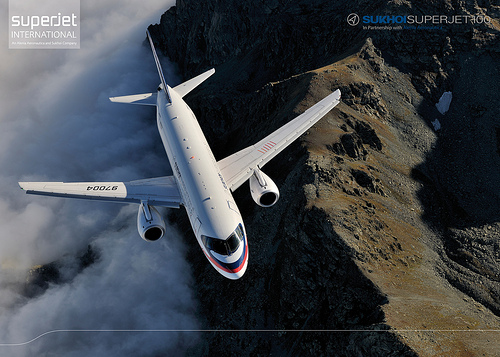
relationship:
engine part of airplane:
[247, 168, 281, 209] [17, 28, 342, 282]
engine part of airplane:
[134, 201, 167, 242] [17, 28, 342, 282]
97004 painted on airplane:
[84, 181, 119, 194] [17, 28, 342, 282]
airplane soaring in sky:
[17, 28, 342, 282] [1, 1, 204, 355]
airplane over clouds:
[17, 28, 342, 282] [8, 63, 105, 163]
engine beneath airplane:
[250, 169, 281, 208] [17, 28, 342, 282]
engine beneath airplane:
[134, 201, 167, 242] [17, 28, 342, 282]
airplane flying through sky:
[17, 28, 342, 282] [1, 1, 204, 355]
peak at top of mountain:
[304, 47, 404, 353] [159, 7, 498, 354]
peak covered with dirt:
[304, 47, 404, 353] [336, 194, 429, 318]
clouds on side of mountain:
[0, 3, 207, 357] [159, 7, 498, 354]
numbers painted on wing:
[86, 185, 119, 191] [17, 174, 183, 208]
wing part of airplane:
[17, 174, 183, 208] [17, 28, 342, 282]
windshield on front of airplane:
[201, 224, 245, 259] [17, 28, 342, 282]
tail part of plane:
[140, 26, 175, 95] [151, 99, 260, 294]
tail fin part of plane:
[169, 68, 213, 103] [151, 99, 260, 294]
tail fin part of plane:
[103, 89, 163, 111] [151, 99, 260, 294]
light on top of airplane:
[187, 154, 196, 162] [17, 28, 342, 282]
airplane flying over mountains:
[17, 28, 342, 279] [141, 1, 499, 355]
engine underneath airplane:
[250, 169, 281, 208] [17, 28, 342, 282]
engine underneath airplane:
[136, 201, 167, 242] [17, 28, 342, 282]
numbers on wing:
[82, 184, 125, 194] [216, 87, 347, 190]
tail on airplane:
[140, 26, 175, 95] [17, 28, 342, 282]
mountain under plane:
[159, 7, 498, 354] [20, 34, 342, 279]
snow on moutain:
[431, 88, 451, 129] [278, 18, 492, 355]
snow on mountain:
[431, 88, 451, 129] [226, 39, 484, 340]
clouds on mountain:
[2, 3, 205, 354] [159, 7, 498, 354]